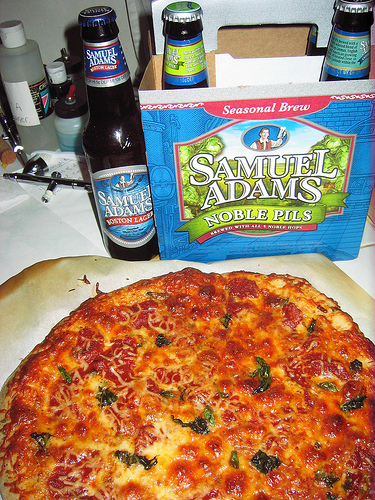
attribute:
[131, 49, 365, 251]
box — red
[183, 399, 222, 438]
basil — green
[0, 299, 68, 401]
crust — homeade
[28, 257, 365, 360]
board — brown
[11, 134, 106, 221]
opener — silver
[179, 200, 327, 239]
ribbon — printed